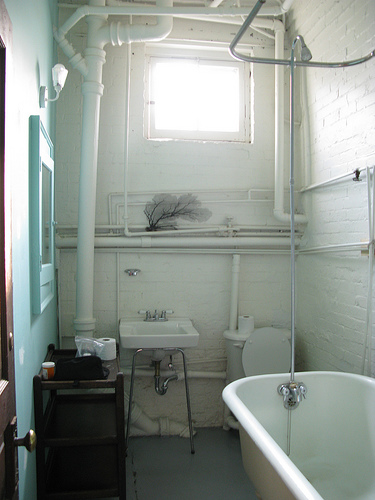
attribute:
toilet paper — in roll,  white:
[96, 337, 116, 359]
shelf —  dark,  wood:
[49, 343, 117, 489]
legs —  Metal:
[126, 348, 195, 455]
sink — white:
[117, 320, 202, 348]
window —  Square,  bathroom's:
[150, 57, 237, 130]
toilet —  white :
[225, 326, 304, 387]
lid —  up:
[246, 334, 293, 374]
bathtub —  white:
[218, 348, 372, 496]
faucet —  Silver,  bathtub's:
[275, 381, 310, 409]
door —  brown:
[2, 26, 29, 480]